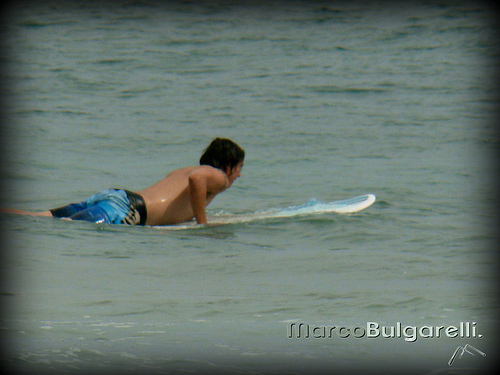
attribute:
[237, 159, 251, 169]
eyebrow — black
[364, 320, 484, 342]
writing — white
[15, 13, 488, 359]
ocean waves — white, blue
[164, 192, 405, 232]
surfboard — white, long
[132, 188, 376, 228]
surfboard — white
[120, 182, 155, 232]
waist — black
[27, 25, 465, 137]
wave — white, blue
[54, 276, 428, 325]
waves — blue, white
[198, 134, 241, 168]
hair — wet, dark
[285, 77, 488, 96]
wave — blue, white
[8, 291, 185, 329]
wave — white, blue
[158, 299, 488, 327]
wave — blue, white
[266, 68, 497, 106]
wave — blue, white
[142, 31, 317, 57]
wave — white, blue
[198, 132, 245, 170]
hair — black